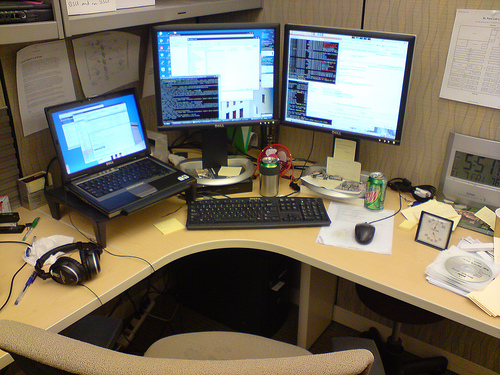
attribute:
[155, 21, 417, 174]
monitors — dual, black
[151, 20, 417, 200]
monitors — dual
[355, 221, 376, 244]
mouse — black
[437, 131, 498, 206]
clock — gray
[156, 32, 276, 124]
screen — on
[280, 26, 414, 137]
computer screen — on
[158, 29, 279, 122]
computer screen — on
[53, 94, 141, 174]
computer screen — on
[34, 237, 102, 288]
headphones — black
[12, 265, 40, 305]
pen — blue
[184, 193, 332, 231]
keyboard — black, rectangular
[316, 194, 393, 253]
paper — white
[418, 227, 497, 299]
paper — white